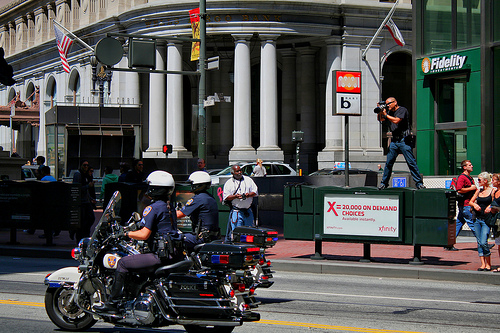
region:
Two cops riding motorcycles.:
[58, 143, 265, 332]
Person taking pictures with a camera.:
[370, 85, 430, 194]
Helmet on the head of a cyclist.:
[139, 169, 184, 208]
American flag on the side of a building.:
[38, 13, 82, 92]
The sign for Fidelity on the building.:
[422, 51, 474, 82]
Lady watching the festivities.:
[460, 162, 497, 260]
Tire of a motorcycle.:
[37, 268, 102, 330]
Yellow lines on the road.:
[271, 307, 335, 331]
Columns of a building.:
[223, 17, 288, 169]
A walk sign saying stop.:
[158, 141, 174, 158]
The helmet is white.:
[143, 173, 178, 203]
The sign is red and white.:
[324, 197, 403, 239]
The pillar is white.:
[260, 36, 281, 160]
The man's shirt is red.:
[451, 173, 481, 210]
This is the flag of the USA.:
[47, 13, 82, 82]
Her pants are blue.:
[468, 214, 494, 257]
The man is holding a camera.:
[365, 96, 427, 182]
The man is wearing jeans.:
[378, 132, 431, 189]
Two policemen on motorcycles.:
[86, 167, 260, 325]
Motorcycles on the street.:
[62, 162, 254, 308]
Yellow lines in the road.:
[263, 309, 350, 332]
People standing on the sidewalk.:
[450, 163, 499, 269]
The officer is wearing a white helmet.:
[182, 166, 222, 196]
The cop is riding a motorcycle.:
[120, 164, 181, 275]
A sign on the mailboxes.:
[302, 183, 410, 246]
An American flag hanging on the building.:
[33, 11, 104, 80]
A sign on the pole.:
[172, 8, 217, 68]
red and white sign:
[329, 66, 374, 126]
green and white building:
[412, 48, 499, 157]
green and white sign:
[293, 175, 473, 237]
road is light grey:
[274, 261, 390, 326]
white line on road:
[261, 280, 353, 301]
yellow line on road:
[265, 308, 382, 332]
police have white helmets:
[140, 160, 225, 200]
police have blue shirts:
[140, 197, 215, 247]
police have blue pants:
[115, 252, 185, 293]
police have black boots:
[100, 273, 135, 331]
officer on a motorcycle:
[99, 167, 182, 308]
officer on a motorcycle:
[161, 167, 218, 272]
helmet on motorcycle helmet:
[144, 170, 174, 193]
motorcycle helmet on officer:
[184, 166, 213, 186]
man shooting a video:
[361, 93, 428, 190]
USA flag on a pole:
[48, 17, 75, 74]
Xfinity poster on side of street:
[314, 189, 403, 241]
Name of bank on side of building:
[425, 53, 467, 70]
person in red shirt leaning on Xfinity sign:
[458, 152, 490, 251]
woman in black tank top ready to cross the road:
[467, 160, 492, 273]